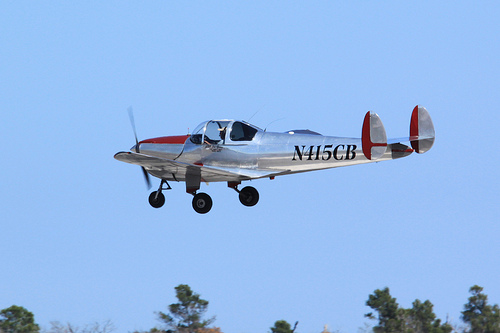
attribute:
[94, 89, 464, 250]
plane — silver, flying, black, spinning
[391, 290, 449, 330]
tree — beautiful, green, pine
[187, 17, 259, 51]
sky — blue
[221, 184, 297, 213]
wheel — black, landing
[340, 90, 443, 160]
tail — fin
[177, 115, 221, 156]
windshield — glass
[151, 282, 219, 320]
trees — top